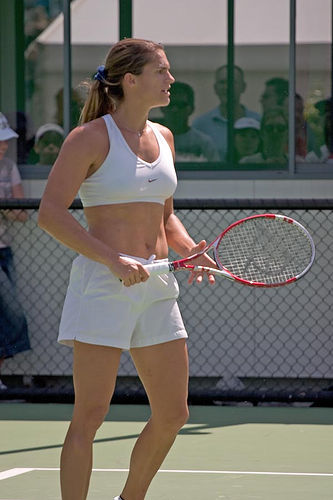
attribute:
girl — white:
[38, 37, 219, 498]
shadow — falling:
[0, 403, 332, 461]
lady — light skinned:
[36, 34, 219, 497]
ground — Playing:
[229, 128, 261, 160]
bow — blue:
[94, 65, 104, 78]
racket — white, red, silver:
[108, 206, 321, 307]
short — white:
[55, 254, 193, 351]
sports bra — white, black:
[73, 106, 180, 214]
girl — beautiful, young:
[219, 107, 263, 171]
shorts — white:
[59, 253, 212, 360]